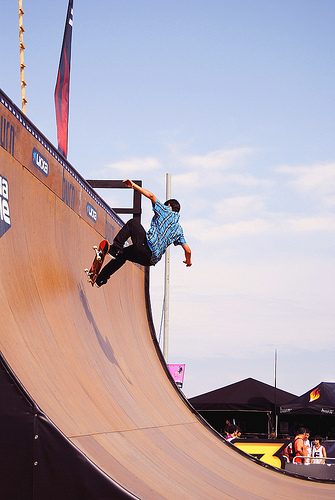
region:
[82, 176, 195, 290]
a boy doing a skateboard trick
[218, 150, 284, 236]
clouds in the sky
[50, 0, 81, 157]
a flag with a flame design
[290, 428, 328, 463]
a group of people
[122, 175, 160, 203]
an arm of a person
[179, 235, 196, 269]
an arm of a person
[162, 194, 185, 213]
the head of a person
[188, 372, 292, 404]
the roof of a building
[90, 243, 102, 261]
the wheels of a skateboard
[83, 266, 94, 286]
the wheels of a skateboard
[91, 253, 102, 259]
wheel of the skateboard.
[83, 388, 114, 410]
wood panels on ramp.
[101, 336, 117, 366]
shadow on the ramp.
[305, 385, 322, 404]
fire logo on tent.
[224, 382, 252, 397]
black canopy on tent.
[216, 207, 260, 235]
clouds in the sky.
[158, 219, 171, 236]
plaid shirt on skater.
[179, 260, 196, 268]
skater's hand in the air.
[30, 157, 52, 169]
design on skate ramp.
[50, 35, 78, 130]
flag on skate ramp.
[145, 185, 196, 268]
Striped shirt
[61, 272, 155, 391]
Shadow on the board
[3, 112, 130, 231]
Logos on the board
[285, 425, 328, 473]
People by the board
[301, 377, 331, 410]
Fire logo on the tent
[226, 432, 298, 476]
Number on the ground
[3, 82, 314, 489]
board is black and brown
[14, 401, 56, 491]
Nails pinning the frabric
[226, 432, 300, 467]
sign is yellow and black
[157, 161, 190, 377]
Silver pole standing tall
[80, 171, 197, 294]
Guy on skateboard in a half pipe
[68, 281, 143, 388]
Shadow of a guy on skateboard in a halfpipe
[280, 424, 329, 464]
Three people standing in background at skating competition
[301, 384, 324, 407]
Flame design on top of a tent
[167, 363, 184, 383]
Part of pink sign in the background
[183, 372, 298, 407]
Top of a black tent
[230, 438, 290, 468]
Large yellow sign in background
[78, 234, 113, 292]
Red design on bottom on a skateboard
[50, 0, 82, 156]
Flag on top of half pipe at skate contest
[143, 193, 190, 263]
Checkered blue button up shirt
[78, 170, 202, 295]
a skater on a slope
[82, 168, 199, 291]
skater on the top of slope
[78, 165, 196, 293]
skater arms are extended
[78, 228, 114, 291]
skateboard is red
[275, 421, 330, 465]
three people are talking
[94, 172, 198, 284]
skater wears a blue shirt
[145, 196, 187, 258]
a squared blue shirt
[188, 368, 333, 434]
homes in front the skate facility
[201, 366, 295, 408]
roof of building is red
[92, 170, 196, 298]
skater wears black pants